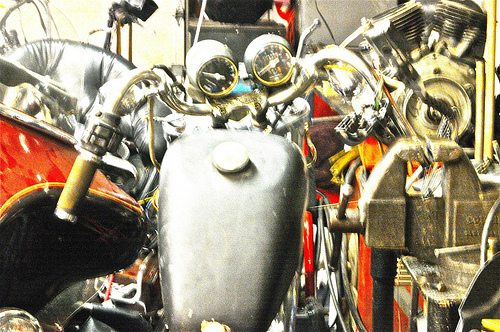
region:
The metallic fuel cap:
[212, 140, 248, 173]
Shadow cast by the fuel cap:
[239, 170, 249, 174]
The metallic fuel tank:
[189, 189, 258, 299]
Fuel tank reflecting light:
[169, 157, 201, 216]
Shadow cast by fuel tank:
[284, 204, 291, 259]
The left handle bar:
[70, 170, 78, 196]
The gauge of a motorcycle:
[209, 63, 226, 88]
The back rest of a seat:
[50, 48, 105, 78]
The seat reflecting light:
[59, 52, 94, 82]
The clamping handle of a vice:
[338, 183, 350, 208]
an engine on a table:
[363, 1, 492, 139]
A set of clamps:
[361, 139, 491, 264]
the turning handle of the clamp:
[323, 180, 354, 272]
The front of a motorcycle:
[56, 33, 390, 329]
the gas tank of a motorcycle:
[157, 128, 308, 328]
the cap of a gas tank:
[210, 138, 250, 171]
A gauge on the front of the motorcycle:
[187, 39, 236, 97]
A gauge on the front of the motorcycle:
[246, 32, 294, 87]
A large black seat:
[7, 40, 165, 177]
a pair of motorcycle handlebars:
[55, 44, 385, 220]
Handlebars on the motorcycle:
[57, 48, 397, 221]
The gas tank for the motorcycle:
[211, 140, 248, 170]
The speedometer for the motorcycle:
[250, 43, 292, 80]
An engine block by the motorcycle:
[368, 5, 485, 137]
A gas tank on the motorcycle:
[167, 135, 298, 325]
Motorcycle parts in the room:
[1, 0, 498, 325]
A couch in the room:
[11, 43, 148, 183]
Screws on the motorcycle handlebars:
[216, 100, 260, 115]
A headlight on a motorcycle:
[1, 306, 41, 330]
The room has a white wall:
[306, 0, 397, 43]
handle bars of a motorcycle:
[52, 23, 448, 248]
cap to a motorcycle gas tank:
[200, 135, 264, 186]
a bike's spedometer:
[232, 30, 302, 90]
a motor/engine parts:
[354, 3, 497, 150]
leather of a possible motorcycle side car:
[0, 28, 160, 198]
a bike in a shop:
[44, 30, 449, 306]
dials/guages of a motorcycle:
[183, 43, 304, 116]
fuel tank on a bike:
[152, 121, 305, 328]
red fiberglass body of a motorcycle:
[0, 125, 155, 305]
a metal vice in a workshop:
[327, 135, 489, 273]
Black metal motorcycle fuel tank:
[152, 133, 321, 328]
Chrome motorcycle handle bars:
[83, 55, 428, 145]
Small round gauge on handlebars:
[181, 50, 241, 99]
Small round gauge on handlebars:
[251, 33, 322, 99]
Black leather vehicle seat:
[14, 31, 160, 181]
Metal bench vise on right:
[359, 115, 497, 257]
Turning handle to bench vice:
[314, 180, 359, 275]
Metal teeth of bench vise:
[385, 128, 474, 166]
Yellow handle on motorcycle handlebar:
[41, 150, 107, 225]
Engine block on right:
[341, 7, 497, 144]